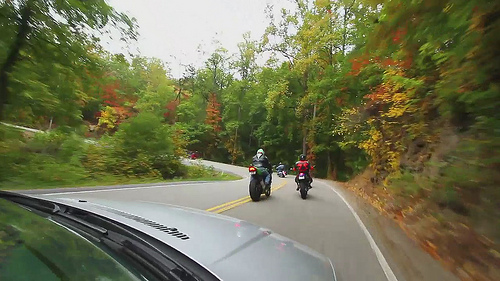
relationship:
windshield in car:
[0, 191, 160, 281] [1, 180, 340, 279]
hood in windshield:
[21, 194, 339, 281] [0, 191, 160, 281]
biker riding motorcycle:
[252, 149, 273, 188] [246, 164, 278, 203]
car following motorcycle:
[0, 188, 336, 281] [244, 150, 270, 175]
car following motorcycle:
[0, 188, 336, 281] [294, 154, 310, 194]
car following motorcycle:
[0, 188, 336, 281] [278, 160, 287, 176]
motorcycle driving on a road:
[289, 165, 316, 200] [183, 185, 236, 207]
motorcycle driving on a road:
[247, 160, 273, 200] [183, 185, 236, 207]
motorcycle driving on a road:
[275, 166, 288, 179] [183, 185, 236, 207]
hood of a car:
[131, 163, 320, 260] [25, 92, 277, 274]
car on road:
[25, 92, 277, 274] [283, 178, 371, 230]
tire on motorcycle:
[247, 180, 262, 202] [247, 160, 273, 200]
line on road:
[214, 192, 261, 220] [6, 123, 409, 280]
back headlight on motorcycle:
[248, 166, 256, 172] [234, 136, 289, 204]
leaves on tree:
[200, 89, 223, 131] [196, 87, 233, 157]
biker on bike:
[252, 149, 273, 188] [246, 164, 274, 201]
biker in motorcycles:
[252, 149, 273, 188] [241, 169, 303, 205]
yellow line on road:
[219, 204, 239, 211] [192, 192, 362, 234]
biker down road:
[250, 147, 272, 187] [2, 120, 462, 279]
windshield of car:
[3, 185, 183, 279] [0, 188, 336, 281]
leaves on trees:
[3, 2, 477, 184] [221, 28, 440, 191]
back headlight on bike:
[245, 165, 257, 172] [249, 164, 273, 201]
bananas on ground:
[337, 170, 455, 270] [4, 114, 467, 279]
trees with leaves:
[246, 3, 498, 259] [352, 6, 487, 104]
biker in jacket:
[292, 155, 314, 190] [287, 154, 315, 177]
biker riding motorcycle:
[292, 155, 314, 190] [286, 151, 317, 198]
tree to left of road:
[3, 3, 67, 91] [0, 116, 386, 268]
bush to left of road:
[4, 121, 90, 180] [0, 116, 386, 268]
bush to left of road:
[109, 110, 177, 172] [0, 116, 386, 268]